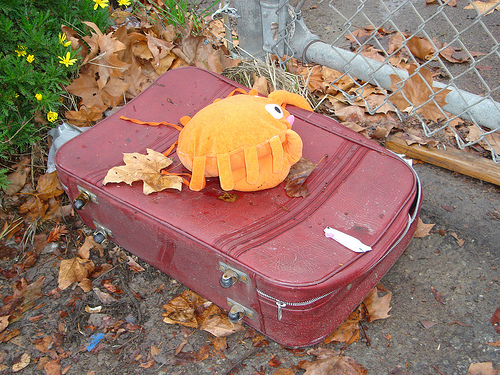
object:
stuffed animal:
[176, 88, 313, 192]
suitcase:
[54, 66, 423, 349]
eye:
[265, 104, 283, 120]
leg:
[189, 156, 207, 191]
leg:
[217, 154, 234, 191]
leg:
[244, 147, 260, 185]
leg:
[269, 136, 283, 174]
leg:
[268, 90, 313, 112]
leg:
[181, 116, 192, 126]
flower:
[91, 0, 109, 11]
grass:
[0, 0, 118, 147]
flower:
[116, 0, 134, 7]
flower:
[15, 45, 28, 57]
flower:
[26, 54, 34, 63]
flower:
[58, 32, 72, 47]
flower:
[58, 52, 77, 68]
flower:
[35, 93, 43, 101]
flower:
[47, 111, 58, 123]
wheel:
[74, 199, 85, 210]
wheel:
[93, 233, 104, 243]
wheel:
[220, 277, 233, 289]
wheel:
[227, 311, 240, 324]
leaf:
[13, 173, 69, 218]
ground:
[0, 160, 500, 375]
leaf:
[56, 245, 92, 291]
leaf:
[388, 64, 452, 123]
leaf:
[365, 290, 392, 323]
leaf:
[161, 289, 246, 338]